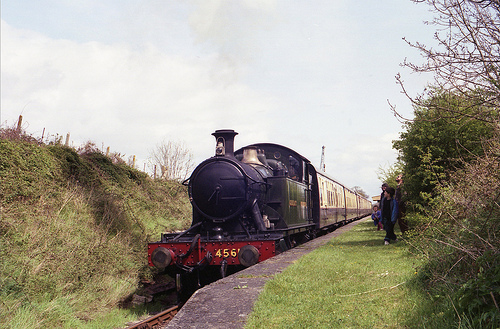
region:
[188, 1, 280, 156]
smoke from steam engine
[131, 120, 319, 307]
large black steam engine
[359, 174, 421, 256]
people standing in field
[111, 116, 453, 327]
people waiting for train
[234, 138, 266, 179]
large metal bell on train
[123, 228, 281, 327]
cow catcher on steam engine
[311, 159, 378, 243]
long line of train cars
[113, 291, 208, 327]
rusty section of train track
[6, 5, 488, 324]
old steam engine in a field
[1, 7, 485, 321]
train travelling through countryside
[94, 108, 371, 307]
A train on train track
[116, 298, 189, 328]
A train track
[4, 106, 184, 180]
A fence with wodden fence post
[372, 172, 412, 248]
People walking on green grass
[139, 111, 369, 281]
Train with black engine with red trim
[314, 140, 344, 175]
A crane in background behind train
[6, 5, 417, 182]
Blue sky with white clouds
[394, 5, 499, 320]
Green trees and shrubs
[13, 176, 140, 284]
Brown weeds in grass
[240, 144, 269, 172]
A silver bell on train engine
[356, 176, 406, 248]
people standing beside train engine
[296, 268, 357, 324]
grass growing beside train tracks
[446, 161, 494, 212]
brown buds on green bush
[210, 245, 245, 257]
yellow numbers on front of train engine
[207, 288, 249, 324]
grey concrete path beside train tracks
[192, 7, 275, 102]
faint black smoke coming from train engine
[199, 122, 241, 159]
black metal smoke stack on train engine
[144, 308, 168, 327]
brown metal train tracks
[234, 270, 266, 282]
row of grass growing on stone path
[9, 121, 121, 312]
hillside covered in grass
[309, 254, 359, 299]
green grass growing beside train tracks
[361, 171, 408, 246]
people standing beside train tracks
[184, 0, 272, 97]
black smoke from train engine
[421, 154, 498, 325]
green bushes beside train tracks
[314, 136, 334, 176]
large metal crane behind train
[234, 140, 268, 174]
large bell on top of train engine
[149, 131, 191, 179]
tree branches with no leaves behind hill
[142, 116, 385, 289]
A train in the foreground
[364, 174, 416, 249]
A small group of people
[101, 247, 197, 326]
Train is on train tracks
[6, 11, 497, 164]
The sky is cloudy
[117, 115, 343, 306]
A front view of a train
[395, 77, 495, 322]
A side view of bushes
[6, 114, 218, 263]
Train is near a small hill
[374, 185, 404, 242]
Person is looking at the train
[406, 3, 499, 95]
Tree in the foreground is bare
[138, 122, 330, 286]
Front of the train is black and red